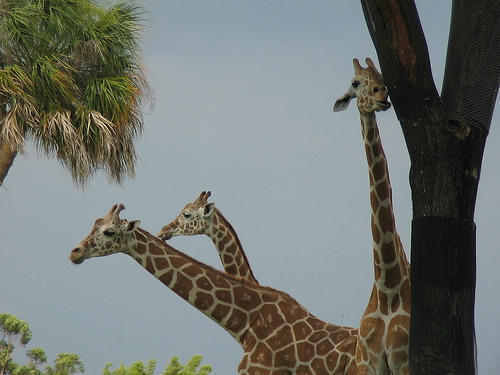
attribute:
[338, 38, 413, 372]
giraffes — three, close together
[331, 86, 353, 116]
ear — giraffe ear, one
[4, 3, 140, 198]
tree — palm, above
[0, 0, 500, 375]
sky — overcast, blue, hazy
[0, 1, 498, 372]
trees — green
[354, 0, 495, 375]
tree — branched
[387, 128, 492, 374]
trunk — brown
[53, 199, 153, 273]
head — giraffe head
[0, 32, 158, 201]
tree — green, brown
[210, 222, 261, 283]
neck — long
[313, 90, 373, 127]
ear — one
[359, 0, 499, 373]
trunk — brown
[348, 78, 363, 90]
eye — one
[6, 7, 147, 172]
tree — green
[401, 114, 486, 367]
trunk — brown, tree trunk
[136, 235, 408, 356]
spots — brown, white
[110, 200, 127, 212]
ear — white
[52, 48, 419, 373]
giraffes — three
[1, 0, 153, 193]
tree top — green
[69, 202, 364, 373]
giraffe — spotted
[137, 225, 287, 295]
mane — brown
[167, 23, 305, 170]
sky — overcast